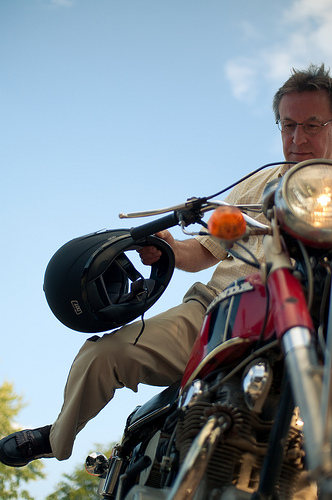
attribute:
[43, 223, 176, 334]
helmet — black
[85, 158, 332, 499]
bike — red, black, black with red, parked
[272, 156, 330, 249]
front light — shining, on, larger, headlight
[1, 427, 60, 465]
shoe — black, loafer, black loafer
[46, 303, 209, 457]
leg — grey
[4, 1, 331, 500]
sky — blue, clear blue, sunny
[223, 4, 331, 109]
clouds — white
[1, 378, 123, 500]
leaves — green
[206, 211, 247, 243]
signal light — orange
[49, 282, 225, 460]
slacks — tan, beige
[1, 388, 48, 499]
tree — taller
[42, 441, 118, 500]
tree — green